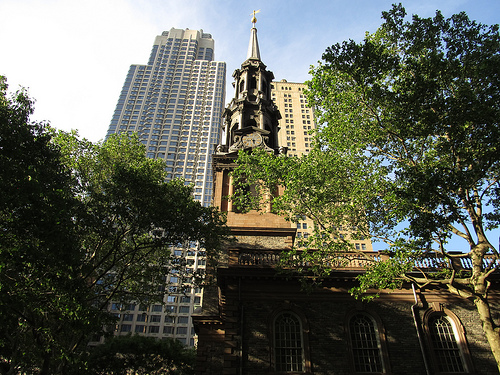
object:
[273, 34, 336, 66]
clouds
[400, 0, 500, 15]
sky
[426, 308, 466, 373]
window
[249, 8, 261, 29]
weather vane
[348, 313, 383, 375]
window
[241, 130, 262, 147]
clock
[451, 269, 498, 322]
tree trunk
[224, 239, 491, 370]
church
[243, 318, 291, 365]
stone building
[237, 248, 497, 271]
stone fence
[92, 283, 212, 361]
building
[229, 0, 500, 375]
tree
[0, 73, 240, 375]
tree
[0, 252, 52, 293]
green leaves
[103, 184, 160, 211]
green leaves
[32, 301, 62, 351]
green leaves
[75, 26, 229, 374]
skyscraper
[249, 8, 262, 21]
cross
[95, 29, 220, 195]
building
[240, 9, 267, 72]
steeple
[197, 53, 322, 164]
building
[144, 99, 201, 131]
wall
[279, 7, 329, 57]
sky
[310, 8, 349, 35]
sky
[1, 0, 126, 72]
cloud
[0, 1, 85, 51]
sky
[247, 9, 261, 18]
top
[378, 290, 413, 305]
exterior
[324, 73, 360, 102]
leaves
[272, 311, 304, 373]
window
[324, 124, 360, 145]
leaves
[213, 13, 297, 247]
tower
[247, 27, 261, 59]
steeple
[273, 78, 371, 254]
building